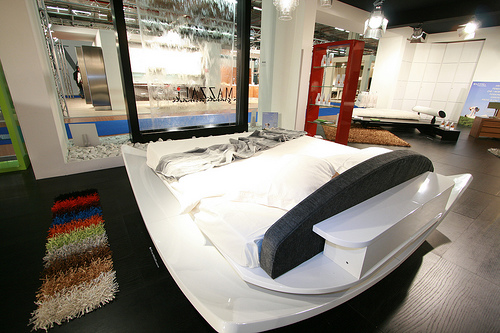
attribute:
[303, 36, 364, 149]
bookshelf — red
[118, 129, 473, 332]
bed — black, white, large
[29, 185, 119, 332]
carpet — multicolored, colorful, small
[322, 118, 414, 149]
carpet — brown, square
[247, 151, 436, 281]
headboard — black, grey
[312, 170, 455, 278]
shelf — white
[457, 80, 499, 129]
poster — blue, green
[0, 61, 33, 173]
bookshelf — green, lime green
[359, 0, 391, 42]
light — silver, on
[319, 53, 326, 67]
bottle — glass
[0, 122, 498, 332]
ground — black, brown, wood, hardwood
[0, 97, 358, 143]
floor — blue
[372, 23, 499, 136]
wall — white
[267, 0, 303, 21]
light — on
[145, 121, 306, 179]
blanket — gray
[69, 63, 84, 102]
person — standing